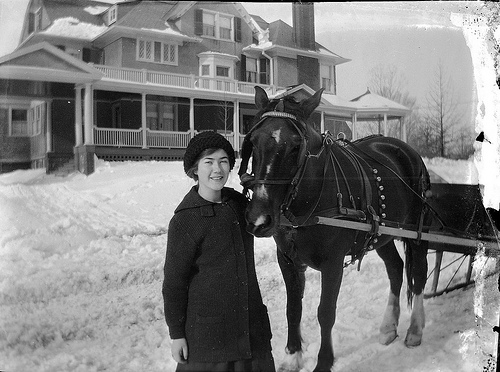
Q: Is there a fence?
A: No, there are no fences.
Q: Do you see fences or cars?
A: No, there are no fences or cars.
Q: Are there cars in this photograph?
A: No, there are no cars.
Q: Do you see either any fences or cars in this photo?
A: No, there are no cars or fences.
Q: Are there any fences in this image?
A: No, there are no fences.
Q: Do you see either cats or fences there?
A: No, there are no fences or cats.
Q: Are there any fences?
A: No, there are no fences.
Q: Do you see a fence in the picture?
A: No, there are no fences.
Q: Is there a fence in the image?
A: No, there are no fences.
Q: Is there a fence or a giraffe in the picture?
A: No, there are no fences or giraffes.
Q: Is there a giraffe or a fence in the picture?
A: No, there are no fences or giraffes.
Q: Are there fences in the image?
A: No, there are no fences.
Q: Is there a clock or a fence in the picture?
A: No, there are no fences or clocks.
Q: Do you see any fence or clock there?
A: No, there are no fences or clocks.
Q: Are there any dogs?
A: No, there are no dogs.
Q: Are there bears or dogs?
A: No, there are no dogs or bears.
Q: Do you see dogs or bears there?
A: No, there are no dogs or bears.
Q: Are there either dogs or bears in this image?
A: No, there are no dogs or bears.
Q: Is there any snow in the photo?
A: Yes, there is snow.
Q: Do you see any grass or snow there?
A: Yes, there is snow.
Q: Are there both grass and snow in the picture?
A: No, there is snow but no grass.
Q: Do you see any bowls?
A: No, there are no bowls.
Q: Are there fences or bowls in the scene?
A: No, there are no bowls or fences.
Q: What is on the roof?
A: The snow is on the roof.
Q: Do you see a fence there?
A: No, there are no fences.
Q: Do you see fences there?
A: No, there are no fences.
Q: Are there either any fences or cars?
A: No, there are no fences or cars.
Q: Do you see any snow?
A: Yes, there is snow.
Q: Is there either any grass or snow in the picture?
A: Yes, there is snow.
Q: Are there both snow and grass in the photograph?
A: No, there is snow but no grass.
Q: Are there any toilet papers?
A: No, there are no toilet papers.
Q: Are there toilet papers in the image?
A: No, there are no toilet papers.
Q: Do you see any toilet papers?
A: No, there are no toilet papers.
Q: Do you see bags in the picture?
A: No, there are no bags.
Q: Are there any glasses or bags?
A: No, there are no bags or glasses.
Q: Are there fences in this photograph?
A: No, there are no fences.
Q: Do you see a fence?
A: No, there are no fences.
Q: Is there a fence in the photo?
A: No, there are no fences.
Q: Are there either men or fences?
A: No, there are no fences or men.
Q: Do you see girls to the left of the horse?
A: Yes, there is a girl to the left of the horse.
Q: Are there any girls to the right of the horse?
A: No, the girl is to the left of the horse.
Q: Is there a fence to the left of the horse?
A: No, there is a girl to the left of the horse.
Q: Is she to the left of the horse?
A: Yes, the girl is to the left of the horse.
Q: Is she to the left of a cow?
A: No, the girl is to the left of the horse.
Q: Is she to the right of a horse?
A: No, the girl is to the left of a horse.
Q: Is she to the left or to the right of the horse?
A: The girl is to the left of the horse.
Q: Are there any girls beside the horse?
A: Yes, there is a girl beside the horse.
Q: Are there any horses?
A: Yes, there is a horse.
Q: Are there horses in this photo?
A: Yes, there is a horse.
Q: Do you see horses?
A: Yes, there is a horse.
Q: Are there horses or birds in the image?
A: Yes, there is a horse.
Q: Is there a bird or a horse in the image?
A: Yes, there is a horse.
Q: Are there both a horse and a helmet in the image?
A: No, there is a horse but no helmets.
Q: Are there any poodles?
A: No, there are no poodles.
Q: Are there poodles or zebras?
A: No, there are no poodles or zebras.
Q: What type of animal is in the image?
A: The animal is a horse.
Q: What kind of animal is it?
A: The animal is a horse.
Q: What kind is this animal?
A: This is a horse.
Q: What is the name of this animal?
A: This is a horse.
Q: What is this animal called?
A: This is a horse.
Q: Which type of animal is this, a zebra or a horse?
A: This is a horse.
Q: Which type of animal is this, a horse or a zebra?
A: This is a horse.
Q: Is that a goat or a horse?
A: That is a horse.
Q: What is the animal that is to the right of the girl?
A: The animal is a horse.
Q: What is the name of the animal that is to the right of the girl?
A: The animal is a horse.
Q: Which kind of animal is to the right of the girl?
A: The animal is a horse.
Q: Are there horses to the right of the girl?
A: Yes, there is a horse to the right of the girl.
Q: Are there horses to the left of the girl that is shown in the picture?
A: No, the horse is to the right of the girl.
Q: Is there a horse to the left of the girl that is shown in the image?
A: No, the horse is to the right of the girl.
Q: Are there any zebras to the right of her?
A: No, there is a horse to the right of the girl.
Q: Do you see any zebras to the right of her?
A: No, there is a horse to the right of the girl.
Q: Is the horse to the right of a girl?
A: Yes, the horse is to the right of a girl.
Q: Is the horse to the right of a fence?
A: No, the horse is to the right of a girl.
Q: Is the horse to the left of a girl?
A: No, the horse is to the right of a girl.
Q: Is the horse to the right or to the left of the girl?
A: The horse is to the right of the girl.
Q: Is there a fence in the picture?
A: No, there are no fences.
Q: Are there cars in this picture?
A: No, there are no cars.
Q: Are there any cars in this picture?
A: No, there are no cars.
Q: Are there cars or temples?
A: No, there are no cars or temples.